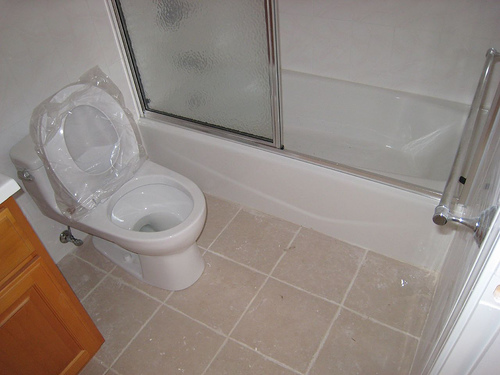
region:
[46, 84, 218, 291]
Toilet is white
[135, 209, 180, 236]
Water in toilet bowl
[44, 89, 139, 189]
Plastic wrapping is clear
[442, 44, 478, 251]
Metal bar near toilet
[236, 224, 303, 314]
Small groove between tiles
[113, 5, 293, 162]
Shower door is clear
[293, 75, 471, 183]
Inside of tub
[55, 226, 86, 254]
Metal piece attached to wall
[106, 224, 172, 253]
Edge of toilet bowl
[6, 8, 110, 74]
Wall behind toilet is white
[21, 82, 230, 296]
white toilet in bathroom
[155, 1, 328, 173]
glass sliding door in bathroom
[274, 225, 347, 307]
tile floor in bathroom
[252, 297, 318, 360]
tile on bathroom room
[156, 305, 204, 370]
tile on bathroom floor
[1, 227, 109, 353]
oak wood bathroom cabinet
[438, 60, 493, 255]
metal handle of bathroom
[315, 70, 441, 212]
white bathtub in room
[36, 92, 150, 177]
lid of white toilet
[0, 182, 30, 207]
corner of bathroom sink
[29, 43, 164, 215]
toilet seat with plastic cover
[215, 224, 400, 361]
floor made of light beige tiles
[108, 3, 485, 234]
bathtub with sliding door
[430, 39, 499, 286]
silver handle bar on wall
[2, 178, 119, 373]
light brown sink cabinet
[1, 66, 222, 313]
white toilet bowl with water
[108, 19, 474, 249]
bathtub is white and empty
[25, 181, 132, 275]
water source on wall behind toilet bowl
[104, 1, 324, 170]
glass is translucid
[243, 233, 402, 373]
color of grout is white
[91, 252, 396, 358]
tan tiles on floor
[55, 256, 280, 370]
debris on floor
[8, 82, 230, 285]
white ceramic toilet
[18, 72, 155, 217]
toilet seat is covered in plastic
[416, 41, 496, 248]
silver towel rack on wall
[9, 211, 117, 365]
wooden vanity next to toilet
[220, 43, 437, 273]
white tub next to toilet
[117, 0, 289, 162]
sliding glass shower door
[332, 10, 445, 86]
white tile behind tub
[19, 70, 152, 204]
toilet seat and lid are up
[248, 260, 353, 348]
the floor is tiled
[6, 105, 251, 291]
the toilet bowl is white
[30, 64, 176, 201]
the toilet seat is up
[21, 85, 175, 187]
plastic on the toilet seat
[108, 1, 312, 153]
the shower door is open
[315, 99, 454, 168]
the tube is white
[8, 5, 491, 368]
the bathroom is clean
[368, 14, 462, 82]
the wall is tiled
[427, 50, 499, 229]
the shower rod is empty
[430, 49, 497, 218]
the shower rod is metal